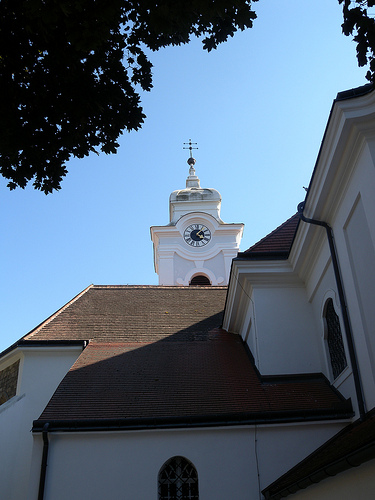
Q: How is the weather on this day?
A: It is sunny.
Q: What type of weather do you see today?
A: It is sunny.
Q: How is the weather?
A: It is sunny.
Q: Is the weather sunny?
A: Yes, it is sunny.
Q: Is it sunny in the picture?
A: Yes, it is sunny.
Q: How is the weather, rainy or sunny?
A: It is sunny.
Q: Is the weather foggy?
A: No, it is sunny.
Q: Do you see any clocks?
A: Yes, there is a clock.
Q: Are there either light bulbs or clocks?
A: Yes, there is a clock.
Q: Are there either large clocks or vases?
A: Yes, there is a large clock.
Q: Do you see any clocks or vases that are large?
A: Yes, the clock is large.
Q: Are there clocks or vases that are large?
A: Yes, the clock is large.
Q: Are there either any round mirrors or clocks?
A: Yes, there is a round clock.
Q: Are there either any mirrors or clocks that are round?
A: Yes, the clock is round.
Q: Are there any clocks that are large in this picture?
A: Yes, there is a large clock.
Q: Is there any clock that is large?
A: Yes, there is a clock that is large.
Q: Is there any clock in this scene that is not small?
A: Yes, there is a large clock.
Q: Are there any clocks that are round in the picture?
A: Yes, there is a round clock.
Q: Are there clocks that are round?
A: Yes, there is a clock that is round.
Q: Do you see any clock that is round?
A: Yes, there is a clock that is round.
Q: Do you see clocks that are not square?
A: Yes, there is a round clock.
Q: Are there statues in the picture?
A: No, there are no statues.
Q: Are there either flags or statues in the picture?
A: No, there are no statues or flags.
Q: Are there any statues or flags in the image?
A: No, there are no statues or flags.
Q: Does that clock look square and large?
A: No, the clock is large but round.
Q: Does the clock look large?
A: Yes, the clock is large.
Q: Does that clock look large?
A: Yes, the clock is large.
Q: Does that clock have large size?
A: Yes, the clock is large.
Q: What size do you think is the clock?
A: The clock is large.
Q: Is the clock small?
A: No, the clock is large.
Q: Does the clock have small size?
A: No, the clock is large.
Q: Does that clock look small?
A: No, the clock is large.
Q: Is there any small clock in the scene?
A: No, there is a clock but it is large.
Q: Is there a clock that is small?
A: No, there is a clock but it is large.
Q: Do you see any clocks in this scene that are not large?
A: No, there is a clock but it is large.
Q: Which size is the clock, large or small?
A: The clock is large.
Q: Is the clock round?
A: Yes, the clock is round.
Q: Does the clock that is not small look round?
A: Yes, the clock is round.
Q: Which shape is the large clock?
A: The clock is round.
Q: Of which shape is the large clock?
A: The clock is round.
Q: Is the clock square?
A: No, the clock is round.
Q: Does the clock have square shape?
A: No, the clock is round.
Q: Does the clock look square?
A: No, the clock is round.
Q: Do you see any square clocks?
A: No, there is a clock but it is round.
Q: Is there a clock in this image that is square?
A: No, there is a clock but it is round.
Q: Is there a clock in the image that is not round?
A: No, there is a clock but it is round.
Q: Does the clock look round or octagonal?
A: The clock is round.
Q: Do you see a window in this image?
A: Yes, there is a window.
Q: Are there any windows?
A: Yes, there is a window.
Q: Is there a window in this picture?
A: Yes, there is a window.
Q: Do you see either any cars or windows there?
A: Yes, there is a window.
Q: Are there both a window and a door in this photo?
A: No, there is a window but no doors.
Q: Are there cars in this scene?
A: No, there are no cars.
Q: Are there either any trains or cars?
A: No, there are no cars or trains.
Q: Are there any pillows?
A: No, there are no pillows.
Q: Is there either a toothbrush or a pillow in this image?
A: No, there are no pillows or toothbrushes.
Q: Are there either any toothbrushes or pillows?
A: No, there are no pillows or toothbrushes.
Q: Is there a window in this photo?
A: Yes, there is a window.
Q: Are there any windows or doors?
A: Yes, there is a window.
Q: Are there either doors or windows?
A: Yes, there is a window.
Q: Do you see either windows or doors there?
A: Yes, there is a window.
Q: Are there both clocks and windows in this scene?
A: Yes, there are both a window and a clock.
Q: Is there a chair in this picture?
A: No, there are no chairs.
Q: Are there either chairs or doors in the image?
A: No, there are no chairs or doors.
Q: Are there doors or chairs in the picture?
A: No, there are no chairs or doors.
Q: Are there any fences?
A: No, there are no fences.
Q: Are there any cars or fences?
A: No, there are no fences or cars.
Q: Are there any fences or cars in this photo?
A: No, there are no cars or fences.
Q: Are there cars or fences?
A: No, there are no cars or fences.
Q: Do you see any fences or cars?
A: No, there are no cars or fences.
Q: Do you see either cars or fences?
A: No, there are no cars or fences.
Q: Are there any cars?
A: No, there are no cars.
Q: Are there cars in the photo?
A: No, there are no cars.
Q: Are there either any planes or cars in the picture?
A: No, there are no cars or planes.